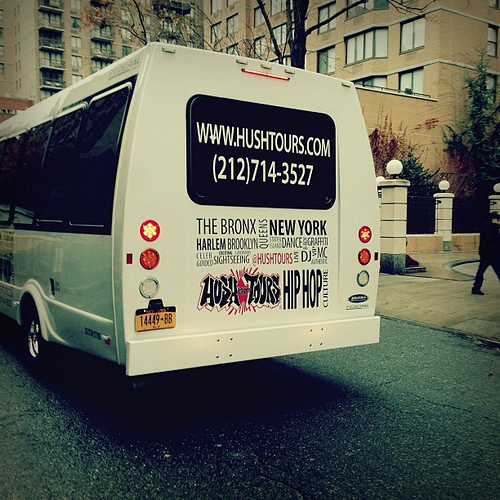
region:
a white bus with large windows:
[0, 56, 387, 397]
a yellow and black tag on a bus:
[126, 302, 184, 339]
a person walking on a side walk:
[463, 205, 497, 295]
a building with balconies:
[25, 9, 105, 106]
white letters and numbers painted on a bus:
[146, 117, 364, 205]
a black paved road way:
[1, 347, 478, 489]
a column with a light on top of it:
[362, 158, 409, 270]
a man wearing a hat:
[476, 199, 498, 257]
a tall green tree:
[422, 40, 498, 226]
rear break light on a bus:
[194, 67, 316, 94]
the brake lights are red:
[116, 208, 372, 264]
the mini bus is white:
[12, 60, 385, 352]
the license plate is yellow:
[114, 294, 189, 329]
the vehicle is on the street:
[5, 47, 415, 406]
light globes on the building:
[362, 144, 417, 184]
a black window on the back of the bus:
[187, 91, 344, 238]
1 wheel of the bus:
[4, 277, 57, 371]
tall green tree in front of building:
[447, 48, 494, 190]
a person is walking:
[457, 185, 499, 316]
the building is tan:
[333, 1, 460, 171]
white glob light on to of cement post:
[385, 159, 403, 177]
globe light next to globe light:
[386, 158, 404, 179]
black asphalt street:
[0, 315, 499, 497]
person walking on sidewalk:
[467, 211, 498, 296]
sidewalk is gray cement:
[377, 271, 499, 346]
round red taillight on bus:
[141, 249, 161, 269]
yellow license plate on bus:
[133, 306, 177, 332]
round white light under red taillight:
[140, 278, 160, 298]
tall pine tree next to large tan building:
[437, 46, 498, 230]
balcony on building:
[38, 57, 67, 72]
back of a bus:
[196, 350, 211, 360]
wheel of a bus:
[28, 340, 40, 349]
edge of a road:
[437, 322, 460, 331]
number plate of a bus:
[139, 322, 172, 323]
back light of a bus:
[354, 254, 370, 271]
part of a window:
[83, 180, 100, 205]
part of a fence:
[421, 185, 428, 198]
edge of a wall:
[393, 210, 403, 218]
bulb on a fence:
[393, 168, 399, 182]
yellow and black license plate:
[131, 307, 181, 334]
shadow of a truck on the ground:
[46, 371, 382, 464]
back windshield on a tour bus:
[183, 89, 348, 214]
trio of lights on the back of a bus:
[126, 214, 165, 302]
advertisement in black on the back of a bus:
[183, 211, 334, 319]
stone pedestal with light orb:
[378, 157, 414, 287]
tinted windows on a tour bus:
[8, 117, 149, 235]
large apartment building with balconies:
[15, 7, 107, 60]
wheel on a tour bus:
[12, 309, 56, 367]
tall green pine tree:
[450, 31, 495, 213]